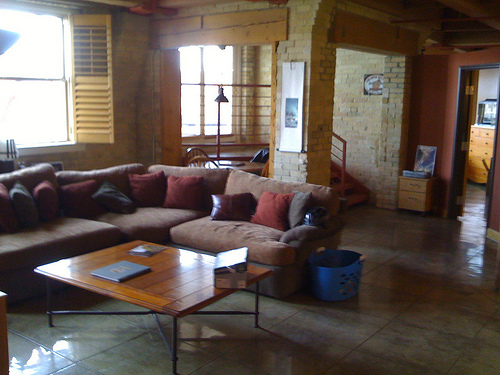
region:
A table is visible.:
[90, 234, 302, 371]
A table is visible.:
[128, 240, 233, 362]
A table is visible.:
[141, 250, 201, 351]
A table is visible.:
[177, 320, 207, 360]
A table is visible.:
[37, 120, 232, 350]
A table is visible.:
[70, 212, 207, 369]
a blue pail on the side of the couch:
[297, 240, 372, 328]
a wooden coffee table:
[40, 217, 265, 326]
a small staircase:
[302, 120, 391, 214]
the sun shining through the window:
[161, 33, 241, 145]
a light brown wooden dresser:
[463, 124, 495, 182]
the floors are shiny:
[10, 321, 98, 371]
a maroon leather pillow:
[173, 175, 255, 225]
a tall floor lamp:
[185, 57, 232, 156]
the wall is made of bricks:
[337, 47, 404, 197]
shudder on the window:
[45, 0, 127, 153]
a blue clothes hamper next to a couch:
[310, 244, 370, 308]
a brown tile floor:
[373, 260, 479, 360]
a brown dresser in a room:
[462, 122, 495, 190]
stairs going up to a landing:
[322, 127, 371, 213]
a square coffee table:
[29, 230, 279, 366]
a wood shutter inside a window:
[54, 4, 123, 156]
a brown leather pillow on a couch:
[202, 186, 256, 223]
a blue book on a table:
[83, 256, 157, 285]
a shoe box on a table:
[205, 242, 256, 296]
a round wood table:
[183, 137, 280, 176]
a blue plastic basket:
[308, 241, 369, 302]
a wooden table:
[41, 237, 269, 313]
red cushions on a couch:
[133, 160, 286, 222]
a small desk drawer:
[398, 175, 431, 212]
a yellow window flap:
[70, 12, 117, 149]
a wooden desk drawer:
[469, 124, 490, 185]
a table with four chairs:
[183, 139, 274, 174]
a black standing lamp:
[213, 80, 236, 149]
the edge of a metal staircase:
[333, 129, 376, 205]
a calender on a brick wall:
[273, 54, 311, 174]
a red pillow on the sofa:
[246, 183, 291, 232]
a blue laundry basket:
[301, 243, 374, 304]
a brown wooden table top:
[34, 237, 275, 325]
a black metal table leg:
[248, 278, 266, 328]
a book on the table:
[88, 254, 163, 289]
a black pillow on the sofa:
[84, 177, 137, 217]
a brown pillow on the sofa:
[201, 188, 256, 225]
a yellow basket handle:
[313, 243, 330, 258]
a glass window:
[0, 13, 81, 150]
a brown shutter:
[65, 11, 121, 148]